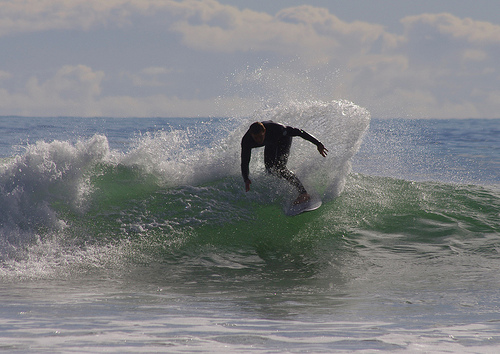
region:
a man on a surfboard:
[172, 89, 360, 299]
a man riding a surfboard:
[199, 101, 382, 229]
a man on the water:
[222, 73, 344, 243]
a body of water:
[22, 82, 487, 343]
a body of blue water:
[75, 136, 488, 317]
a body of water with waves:
[94, 126, 419, 350]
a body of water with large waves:
[60, 105, 440, 340]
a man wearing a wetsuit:
[175, 91, 357, 261]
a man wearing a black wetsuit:
[216, 87, 385, 272]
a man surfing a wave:
[237, 81, 464, 308]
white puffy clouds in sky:
[1, 0, 497, 116]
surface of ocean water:
[1, 119, 498, 181]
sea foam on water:
[0, 298, 494, 352]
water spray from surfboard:
[239, 99, 372, 200]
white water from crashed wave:
[1, 135, 113, 251]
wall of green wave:
[99, 170, 487, 257]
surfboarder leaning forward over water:
[235, 116, 325, 217]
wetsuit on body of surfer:
[241, 120, 319, 192]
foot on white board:
[286, 193, 321, 217]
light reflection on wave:
[183, 185, 496, 301]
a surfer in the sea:
[230, 109, 335, 224]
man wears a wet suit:
[234, 115, 337, 222]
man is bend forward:
[228, 113, 335, 217]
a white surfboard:
[275, 183, 327, 220]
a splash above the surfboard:
[222, 80, 372, 225]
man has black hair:
[229, 112, 284, 155]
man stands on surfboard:
[226, 98, 336, 227]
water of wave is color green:
[31, 151, 494, 264]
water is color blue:
[358, 112, 496, 163]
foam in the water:
[4, 287, 499, 349]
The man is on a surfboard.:
[210, 80, 360, 220]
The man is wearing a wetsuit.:
[210, 105, 350, 230]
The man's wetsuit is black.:
[205, 95, 351, 240]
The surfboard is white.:
[206, 95, 362, 235]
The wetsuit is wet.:
[195, 85, 375, 237]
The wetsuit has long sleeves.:
[202, 102, 352, 232]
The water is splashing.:
[1, 107, 496, 352]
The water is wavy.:
[3, 110, 499, 352]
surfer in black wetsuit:
[238, 115, 330, 212]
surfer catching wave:
[238, 114, 333, 218]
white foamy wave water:
[1, 62, 385, 277]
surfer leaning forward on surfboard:
[231, 111, 336, 215]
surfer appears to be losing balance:
[234, 118, 329, 208]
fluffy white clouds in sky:
[0, 3, 499, 118]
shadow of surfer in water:
[179, 238, 351, 321]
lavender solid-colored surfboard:
[290, 175, 327, 218]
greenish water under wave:
[97, 169, 499, 289]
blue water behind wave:
[0, 113, 499, 188]